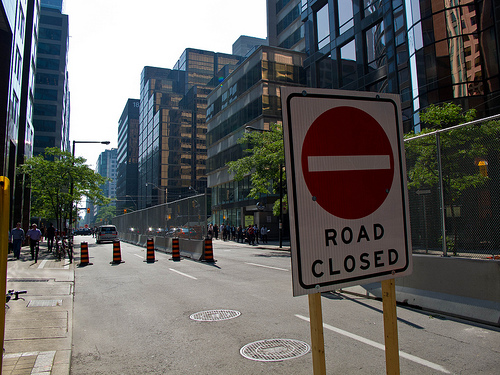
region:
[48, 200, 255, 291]
row of road barriers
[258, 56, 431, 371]
a white sign on poles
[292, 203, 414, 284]
black writing on sign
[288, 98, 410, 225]
red circle on sign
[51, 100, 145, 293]
street lamp in background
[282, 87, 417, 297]
a road closed traffic sign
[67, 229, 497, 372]
a paved city street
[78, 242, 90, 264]
a red and black traffic cone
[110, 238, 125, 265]
a red and black traffic cone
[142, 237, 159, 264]
a red and black traffic cone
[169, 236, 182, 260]
a red and black traffic cone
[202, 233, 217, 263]
a red and black traffic cone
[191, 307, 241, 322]
a man hole cover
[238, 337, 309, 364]
a man hole cover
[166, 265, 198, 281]
a painted white lane marker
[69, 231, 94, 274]
a striped traffic cone in road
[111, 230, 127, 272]
a striped traffic cone in road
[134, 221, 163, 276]
a striped traffic cone in road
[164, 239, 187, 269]
a striped traffic cone in road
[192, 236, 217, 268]
a striped traffic cone in road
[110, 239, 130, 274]
traffic cone is orange and black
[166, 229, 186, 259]
traffic cone is orange and black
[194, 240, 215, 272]
traffic cone is orange and black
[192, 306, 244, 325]
a man hole cover on a road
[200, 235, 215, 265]
black and orange caution barrel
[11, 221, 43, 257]
two men walking on a sidewalk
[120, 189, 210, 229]
a metal chain link fence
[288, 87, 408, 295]
a white, red and black sign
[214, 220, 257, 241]
several people on a sidewalk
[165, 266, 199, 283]
a white line painted on a street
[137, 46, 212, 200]
a tall building with sevear levels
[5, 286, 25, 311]
a bicycle handle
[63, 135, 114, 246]
a tall street light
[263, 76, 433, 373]
There is a sign that reads the road is closed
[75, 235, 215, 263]
there are traffic pylons that are orange and black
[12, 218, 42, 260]
There are two men walking on the sidewalk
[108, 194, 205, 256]
there is a large fence in the center of the road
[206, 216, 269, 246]
there are many people on the sidewalk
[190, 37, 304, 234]
There is a tan multi story building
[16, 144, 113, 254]
There is a tree with green leaves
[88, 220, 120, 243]
there is a silver car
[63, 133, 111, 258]
There is a street lamp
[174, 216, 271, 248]
people at the sidewalk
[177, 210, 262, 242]
people at the sidewalk